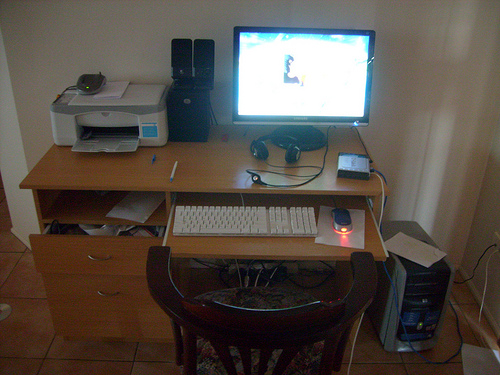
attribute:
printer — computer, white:
[12, 44, 190, 166]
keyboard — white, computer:
[159, 184, 336, 252]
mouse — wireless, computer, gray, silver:
[311, 211, 364, 244]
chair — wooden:
[109, 256, 418, 364]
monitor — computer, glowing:
[207, 18, 393, 147]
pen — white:
[144, 153, 202, 195]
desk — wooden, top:
[4, 94, 405, 249]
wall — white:
[10, 15, 135, 79]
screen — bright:
[264, 51, 350, 112]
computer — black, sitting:
[375, 253, 470, 366]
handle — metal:
[87, 246, 121, 265]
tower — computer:
[379, 277, 459, 348]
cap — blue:
[138, 139, 169, 173]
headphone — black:
[232, 134, 322, 174]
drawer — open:
[11, 205, 162, 284]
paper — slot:
[83, 180, 182, 239]